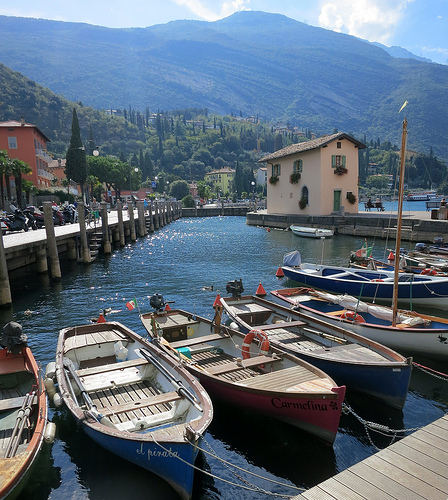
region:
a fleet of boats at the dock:
[19, 274, 446, 467]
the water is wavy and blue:
[222, 429, 300, 489]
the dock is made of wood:
[296, 471, 419, 497]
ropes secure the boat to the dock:
[142, 404, 272, 496]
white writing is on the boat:
[118, 421, 203, 495]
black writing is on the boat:
[252, 394, 349, 440]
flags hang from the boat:
[74, 274, 279, 418]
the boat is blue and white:
[277, 256, 442, 309]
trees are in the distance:
[16, 104, 282, 173]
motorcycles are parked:
[10, 198, 128, 222]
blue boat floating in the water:
[56, 320, 210, 499]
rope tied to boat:
[150, 433, 297, 498]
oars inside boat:
[139, 345, 203, 414]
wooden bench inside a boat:
[76, 357, 147, 380]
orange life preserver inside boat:
[240, 329, 269, 362]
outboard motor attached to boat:
[148, 292, 177, 311]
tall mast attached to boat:
[387, 221, 402, 326]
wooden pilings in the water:
[42, 200, 63, 282]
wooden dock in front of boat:
[281, 412, 447, 499]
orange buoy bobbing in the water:
[254, 283, 267, 296]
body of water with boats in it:
[47, 220, 432, 453]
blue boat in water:
[55, 310, 217, 485]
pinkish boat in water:
[136, 285, 342, 413]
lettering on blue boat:
[136, 443, 185, 464]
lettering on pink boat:
[260, 394, 341, 415]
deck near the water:
[313, 405, 447, 499]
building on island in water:
[249, 126, 373, 214]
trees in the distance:
[126, 108, 270, 147]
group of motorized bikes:
[11, 192, 85, 227]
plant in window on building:
[331, 166, 352, 177]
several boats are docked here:
[2, 222, 444, 489]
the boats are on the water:
[0, 210, 438, 482]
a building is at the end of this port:
[243, 125, 367, 242]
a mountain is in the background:
[50, 7, 431, 108]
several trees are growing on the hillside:
[29, 80, 421, 177]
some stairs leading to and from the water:
[85, 226, 101, 266]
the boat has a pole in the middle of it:
[390, 109, 407, 331]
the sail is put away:
[308, 286, 408, 323]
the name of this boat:
[117, 444, 178, 463]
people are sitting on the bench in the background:
[361, 187, 385, 214]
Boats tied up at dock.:
[38, 292, 379, 494]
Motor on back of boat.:
[142, 288, 174, 316]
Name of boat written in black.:
[266, 391, 335, 421]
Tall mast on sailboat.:
[389, 114, 413, 337]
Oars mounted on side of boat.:
[134, 344, 206, 421]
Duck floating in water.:
[195, 277, 220, 294]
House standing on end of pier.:
[256, 127, 369, 219]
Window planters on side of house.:
[265, 169, 309, 186]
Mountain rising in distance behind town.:
[98, 5, 446, 144]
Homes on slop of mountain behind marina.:
[103, 100, 282, 146]